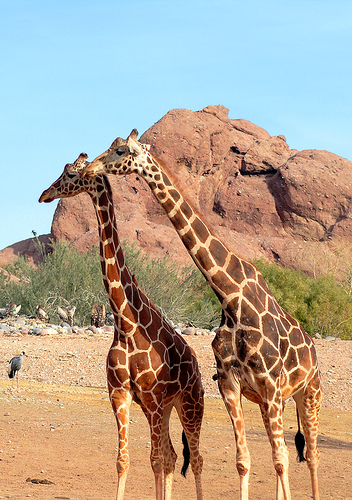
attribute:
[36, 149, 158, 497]
giraffe — with ears, here, spotted, with tail, tall tan, tall tan spotted, with long tan leg, side by side, looking left, with brown spots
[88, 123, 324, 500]
giraffe — spotted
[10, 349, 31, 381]
bird — on rocky soil, on dirt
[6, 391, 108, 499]
soil — tan brown dry, with bushes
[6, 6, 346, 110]
sky — white clouded, clear blue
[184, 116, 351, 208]
rock — large tan, on hill, in front of bush, with red top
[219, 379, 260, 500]
leg — long tan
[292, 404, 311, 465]
tail — with black hair